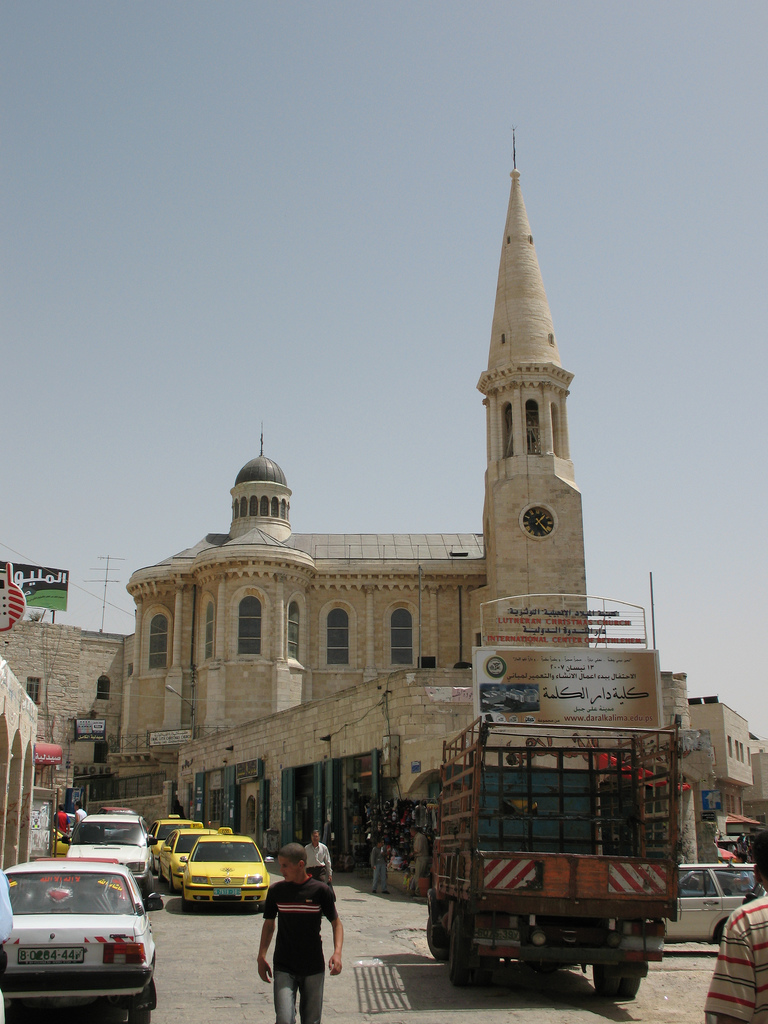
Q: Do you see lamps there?
A: No, there are no lamps.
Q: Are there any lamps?
A: No, there are no lamps.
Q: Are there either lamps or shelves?
A: No, there are no lamps or shelves.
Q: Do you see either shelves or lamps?
A: No, there are no lamps or shelves.